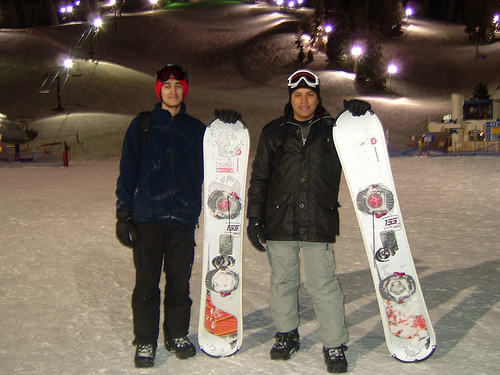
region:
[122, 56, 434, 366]
two people posing with snow boards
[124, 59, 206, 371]
a guy with a red hat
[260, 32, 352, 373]
a guy with a black hat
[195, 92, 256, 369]
a long and slim snow board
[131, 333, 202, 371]
a pair of snow shoes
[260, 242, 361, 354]
a pair of grey snow pants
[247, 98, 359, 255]
a thick and black winter jacket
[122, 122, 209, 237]
a thick and blue winter jacket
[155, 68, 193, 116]
the face of a teenager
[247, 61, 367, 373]
man on right standing on the snow.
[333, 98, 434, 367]
man on right holding snow board.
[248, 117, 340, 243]
man with black coat.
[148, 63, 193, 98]
red hat on the man's head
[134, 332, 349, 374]
men have on black boots.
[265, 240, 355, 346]
man on right has on gray pants.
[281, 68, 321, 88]
white snow goggles are on man's head.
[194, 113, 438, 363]
snow boards have decals.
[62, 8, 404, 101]
lights are on the ski slope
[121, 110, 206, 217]
man on left has on blue jacket.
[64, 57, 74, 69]
white colored glowing light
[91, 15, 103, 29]
white colored glowing light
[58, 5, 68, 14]
white colored glowing light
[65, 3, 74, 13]
white colored glowing light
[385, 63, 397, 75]
white colored glowing light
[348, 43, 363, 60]
white colored glowing light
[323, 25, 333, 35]
white colored glowing light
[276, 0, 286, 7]
white colored glowing light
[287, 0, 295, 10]
white colored glowing light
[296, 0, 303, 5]
white colored glowing light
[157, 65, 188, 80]
man wearing black eye gear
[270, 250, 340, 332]
man wearing grey pant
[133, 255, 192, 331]
man wearing black pant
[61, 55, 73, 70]
light lit on pole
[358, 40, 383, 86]
tree visible at distance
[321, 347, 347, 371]
man wearing black shoe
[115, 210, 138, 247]
man wearing black hand gloves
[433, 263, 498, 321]
shadow falling on ground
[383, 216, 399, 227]
155 mentioned on broard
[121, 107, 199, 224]
man wearing blue jacket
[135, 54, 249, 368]
person standing with snowboard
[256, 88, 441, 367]
person standing with snowboard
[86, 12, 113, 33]
light on the slopes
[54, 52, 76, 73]
light on the slopes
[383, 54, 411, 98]
light on the slopes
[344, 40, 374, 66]
light on the slopes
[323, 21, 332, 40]
light on the slopes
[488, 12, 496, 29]
light on the slopes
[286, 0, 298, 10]
light on the slopes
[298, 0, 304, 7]
light on the slopes